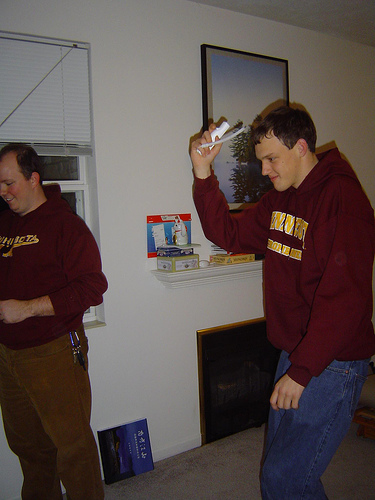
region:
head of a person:
[238, 105, 319, 198]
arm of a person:
[185, 136, 281, 249]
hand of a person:
[190, 122, 231, 156]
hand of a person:
[270, 368, 318, 414]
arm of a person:
[306, 236, 352, 356]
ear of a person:
[287, 135, 321, 173]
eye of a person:
[253, 146, 281, 189]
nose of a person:
[256, 156, 270, 186]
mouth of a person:
[266, 165, 280, 182]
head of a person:
[2, 125, 59, 225]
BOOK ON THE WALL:
[111, 423, 150, 481]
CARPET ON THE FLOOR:
[200, 454, 223, 490]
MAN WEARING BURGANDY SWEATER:
[283, 291, 316, 308]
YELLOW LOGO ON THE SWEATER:
[271, 214, 308, 260]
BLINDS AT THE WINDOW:
[56, 103, 80, 134]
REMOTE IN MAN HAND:
[213, 124, 220, 134]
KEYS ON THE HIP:
[73, 330, 85, 364]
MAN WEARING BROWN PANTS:
[42, 369, 62, 405]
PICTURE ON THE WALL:
[207, 44, 273, 97]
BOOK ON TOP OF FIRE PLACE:
[216, 254, 255, 260]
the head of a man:
[247, 100, 319, 197]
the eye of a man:
[256, 146, 292, 179]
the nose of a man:
[258, 153, 279, 196]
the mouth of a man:
[260, 160, 295, 195]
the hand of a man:
[268, 356, 323, 423]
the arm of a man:
[272, 182, 370, 428]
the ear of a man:
[249, 132, 320, 215]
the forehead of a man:
[240, 83, 307, 178]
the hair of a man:
[244, 66, 339, 204]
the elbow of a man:
[197, 196, 275, 273]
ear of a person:
[293, 134, 317, 154]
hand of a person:
[253, 362, 309, 421]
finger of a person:
[270, 383, 301, 408]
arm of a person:
[283, 278, 363, 368]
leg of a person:
[250, 373, 358, 491]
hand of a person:
[184, 121, 241, 182]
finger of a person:
[199, 126, 224, 152]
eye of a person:
[268, 152, 281, 162]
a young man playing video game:
[189, 106, 374, 496]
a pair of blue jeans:
[258, 351, 371, 497]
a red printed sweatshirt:
[189, 148, 372, 386]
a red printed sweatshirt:
[0, 183, 108, 349]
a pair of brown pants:
[0, 324, 103, 498]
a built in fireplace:
[195, 316, 281, 447]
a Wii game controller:
[195, 117, 246, 154]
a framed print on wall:
[200, 42, 290, 216]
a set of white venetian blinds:
[0, 32, 93, 157]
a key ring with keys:
[66, 330, 85, 369]